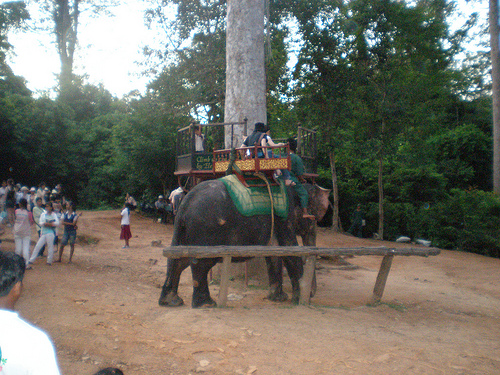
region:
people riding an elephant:
[186, 120, 309, 230]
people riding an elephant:
[159, 75, 366, 268]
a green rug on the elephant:
[207, 161, 306, 246]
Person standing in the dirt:
[110, 188, 140, 248]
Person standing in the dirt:
[59, 201, 86, 260]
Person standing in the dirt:
[35, 197, 62, 266]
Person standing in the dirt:
[8, 187, 38, 262]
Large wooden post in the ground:
[165, 231, 478, 342]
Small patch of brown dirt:
[76, 320, 118, 362]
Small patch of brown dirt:
[151, 326, 191, 372]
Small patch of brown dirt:
[235, 333, 275, 374]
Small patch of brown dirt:
[312, 340, 324, 358]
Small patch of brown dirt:
[351, 336, 384, 371]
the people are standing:
[12, 171, 94, 268]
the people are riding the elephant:
[155, 115, 327, 314]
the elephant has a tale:
[160, 220, 183, 292]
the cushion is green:
[230, 187, 299, 217]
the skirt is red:
[116, 222, 133, 242]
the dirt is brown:
[185, 321, 350, 358]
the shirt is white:
[116, 205, 132, 225]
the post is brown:
[160, 237, 440, 307]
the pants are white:
[25, 231, 63, 270]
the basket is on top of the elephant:
[199, 140, 293, 182]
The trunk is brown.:
[224, 3, 269, 156]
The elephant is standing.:
[156, 164, 331, 317]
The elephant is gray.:
[165, 176, 340, 318]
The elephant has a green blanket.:
[155, 170, 349, 310]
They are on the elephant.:
[237, 112, 309, 187]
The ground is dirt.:
[4, 203, 499, 368]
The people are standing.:
[4, 178, 88, 262]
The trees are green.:
[267, 1, 496, 251]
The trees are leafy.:
[280, 0, 496, 251]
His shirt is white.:
[0, 305, 60, 372]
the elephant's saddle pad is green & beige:
[201, 136, 340, 233]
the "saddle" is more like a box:
[207, 135, 299, 180]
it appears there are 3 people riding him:
[236, 114, 336, 219]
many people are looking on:
[8, 183, 83, 265]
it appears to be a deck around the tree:
[170, 113, 343, 183]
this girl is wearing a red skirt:
[117, 203, 138, 245]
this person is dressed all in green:
[284, 148, 316, 218]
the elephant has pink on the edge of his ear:
[310, 182, 334, 222]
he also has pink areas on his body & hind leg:
[191, 210, 226, 298]